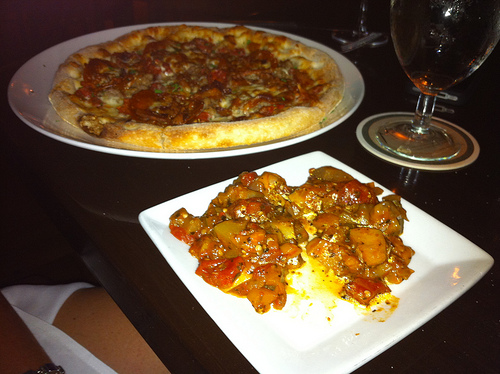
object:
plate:
[137, 151, 495, 372]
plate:
[9, 21, 367, 161]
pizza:
[50, 23, 345, 155]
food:
[171, 167, 413, 311]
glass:
[375, 0, 500, 163]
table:
[9, 3, 498, 372]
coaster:
[357, 112, 480, 173]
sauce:
[98, 97, 142, 122]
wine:
[393, 23, 498, 92]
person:
[0, 282, 168, 372]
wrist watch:
[27, 365, 64, 372]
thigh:
[54, 286, 168, 372]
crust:
[117, 116, 312, 151]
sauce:
[316, 262, 343, 297]